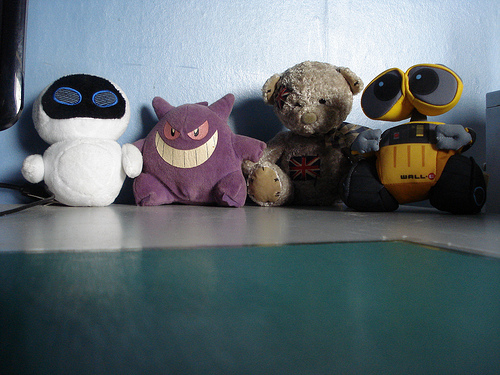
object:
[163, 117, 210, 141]
eyes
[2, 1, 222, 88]
wall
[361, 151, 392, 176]
ground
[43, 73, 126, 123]
face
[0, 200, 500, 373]
table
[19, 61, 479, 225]
toys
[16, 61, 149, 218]
animal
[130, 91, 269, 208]
toy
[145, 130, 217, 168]
teeth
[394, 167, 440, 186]
flag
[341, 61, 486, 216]
stuffed animal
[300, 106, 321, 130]
nose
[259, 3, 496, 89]
wall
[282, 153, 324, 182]
flag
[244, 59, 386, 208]
bear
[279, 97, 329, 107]
eyes